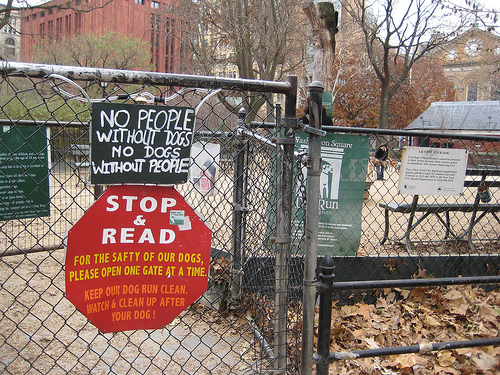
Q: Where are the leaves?
A: Beside the gate.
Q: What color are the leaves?
A: Brown.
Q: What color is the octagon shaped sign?
A: Red.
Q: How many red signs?
A: One.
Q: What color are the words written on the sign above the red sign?
A: White.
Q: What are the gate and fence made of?
A: Metal.